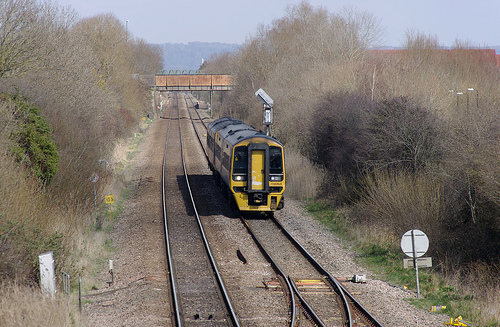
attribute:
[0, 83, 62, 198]
tree — green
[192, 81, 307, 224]
train — black, yellow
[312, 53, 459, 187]
trees — brown, leafless